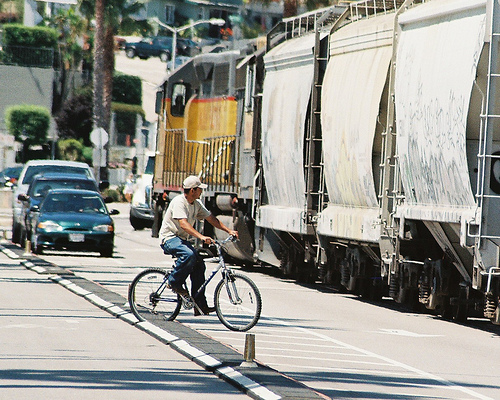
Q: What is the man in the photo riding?
A: A bike.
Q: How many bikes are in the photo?
A: One.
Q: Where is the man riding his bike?
A: The street.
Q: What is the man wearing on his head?
A: Hat.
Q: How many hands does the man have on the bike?
A: Two.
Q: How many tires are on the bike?
A: Two.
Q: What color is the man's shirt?
A: White.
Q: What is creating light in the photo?
A: Sunshine.